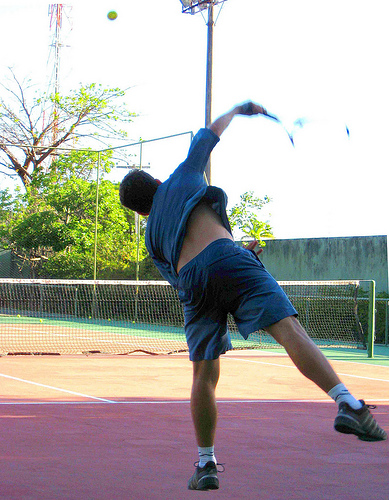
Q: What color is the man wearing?
A: Blue.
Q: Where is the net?
A: In the center of the court.